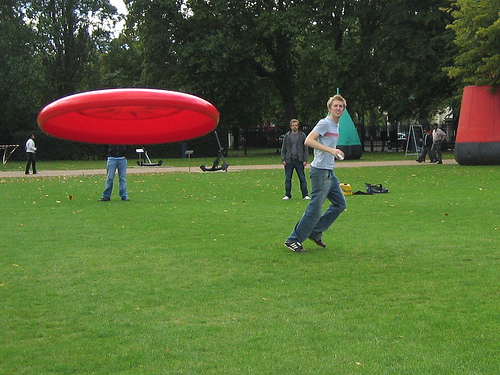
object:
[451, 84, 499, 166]
pole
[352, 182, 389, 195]
backpack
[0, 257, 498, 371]
grass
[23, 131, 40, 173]
person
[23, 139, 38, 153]
shirt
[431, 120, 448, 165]
people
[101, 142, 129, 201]
people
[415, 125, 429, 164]
people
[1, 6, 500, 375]
park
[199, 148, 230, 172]
anchor decor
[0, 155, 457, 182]
sidewalk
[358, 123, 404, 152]
gate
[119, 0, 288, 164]
trees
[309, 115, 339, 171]
shirt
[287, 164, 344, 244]
jeans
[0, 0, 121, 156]
tree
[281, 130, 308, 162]
jacket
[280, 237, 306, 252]
shoe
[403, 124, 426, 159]
swing set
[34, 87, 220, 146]
frisbee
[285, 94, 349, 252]
boy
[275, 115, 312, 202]
man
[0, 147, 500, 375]
field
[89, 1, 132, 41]
light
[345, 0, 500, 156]
trees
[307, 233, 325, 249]
shoe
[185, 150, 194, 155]
metal plaque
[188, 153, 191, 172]
pole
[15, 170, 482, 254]
ground